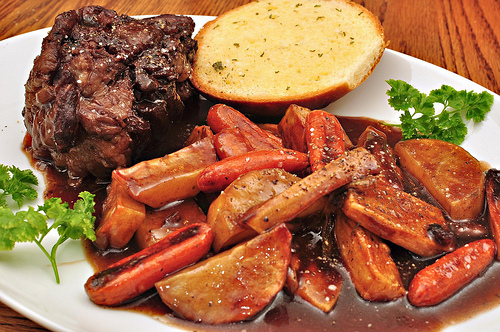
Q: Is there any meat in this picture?
A: Yes, there is meat.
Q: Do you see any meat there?
A: Yes, there is meat.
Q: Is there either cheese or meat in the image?
A: Yes, there is meat.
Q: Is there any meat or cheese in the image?
A: Yes, there is meat.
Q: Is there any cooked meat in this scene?
A: Yes, there is cooked meat.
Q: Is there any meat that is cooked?
A: Yes, there is meat that is cooked.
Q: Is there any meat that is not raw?
A: Yes, there is cooked meat.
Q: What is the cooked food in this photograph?
A: The food is meat.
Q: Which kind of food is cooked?
A: The food is meat.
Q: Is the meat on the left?
A: Yes, the meat is on the left of the image.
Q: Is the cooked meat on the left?
A: Yes, the meat is on the left of the image.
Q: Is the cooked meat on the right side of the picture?
A: No, the meat is on the left of the image.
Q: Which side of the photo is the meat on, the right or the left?
A: The meat is on the left of the image.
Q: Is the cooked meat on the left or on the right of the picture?
A: The meat is on the left of the image.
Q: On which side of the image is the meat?
A: The meat is on the left of the image.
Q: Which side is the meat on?
A: The meat is on the left of the image.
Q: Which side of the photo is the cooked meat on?
A: The meat is on the left of the image.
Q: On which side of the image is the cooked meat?
A: The meat is on the left of the image.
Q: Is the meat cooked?
A: Yes, the meat is cooked.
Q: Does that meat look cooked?
A: Yes, the meat is cooked.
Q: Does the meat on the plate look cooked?
A: Yes, the meat is cooked.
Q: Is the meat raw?
A: No, the meat is cooked.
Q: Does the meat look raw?
A: No, the meat is cooked.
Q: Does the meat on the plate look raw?
A: No, the meat is cooked.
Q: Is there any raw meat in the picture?
A: No, there is meat but it is cooked.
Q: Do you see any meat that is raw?
A: No, there is meat but it is cooked.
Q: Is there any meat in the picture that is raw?
A: No, there is meat but it is cooked.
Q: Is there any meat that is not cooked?
A: No, there is meat but it is cooked.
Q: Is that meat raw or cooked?
A: The meat is cooked.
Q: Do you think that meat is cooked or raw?
A: The meat is cooked.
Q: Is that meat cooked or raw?
A: The meat is cooked.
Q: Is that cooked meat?
A: Yes, that is cooked meat.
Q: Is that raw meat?
A: No, that is cooked meat.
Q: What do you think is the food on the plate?
A: The food is meat.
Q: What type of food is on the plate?
A: The food is meat.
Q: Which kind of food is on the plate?
A: The food is meat.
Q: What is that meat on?
A: The meat is on the plate.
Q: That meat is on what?
A: The meat is on the plate.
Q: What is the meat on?
A: The meat is on the plate.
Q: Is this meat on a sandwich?
A: No, the meat is on the plate.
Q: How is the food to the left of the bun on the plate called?
A: The food is meat.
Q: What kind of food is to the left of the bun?
A: The food is meat.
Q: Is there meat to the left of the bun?
A: Yes, there is meat to the left of the bun.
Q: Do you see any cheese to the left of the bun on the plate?
A: No, there is meat to the left of the bun.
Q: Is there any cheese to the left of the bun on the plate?
A: No, there is meat to the left of the bun.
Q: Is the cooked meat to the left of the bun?
A: Yes, the meat is to the left of the bun.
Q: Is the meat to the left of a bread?
A: No, the meat is to the left of the bun.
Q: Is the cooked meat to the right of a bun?
A: No, the meat is to the left of a bun.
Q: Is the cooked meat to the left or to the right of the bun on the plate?
A: The meat is to the left of the bun.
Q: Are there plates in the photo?
A: Yes, there is a plate.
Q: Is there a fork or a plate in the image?
A: Yes, there is a plate.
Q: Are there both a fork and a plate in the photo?
A: No, there is a plate but no forks.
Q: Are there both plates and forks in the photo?
A: No, there is a plate but no forks.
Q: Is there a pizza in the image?
A: No, there are no pizzas.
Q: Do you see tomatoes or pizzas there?
A: No, there are no pizzas or tomatoes.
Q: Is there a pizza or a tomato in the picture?
A: No, there are no pizzas or tomatoes.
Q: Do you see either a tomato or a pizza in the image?
A: No, there are no pizzas or tomatoes.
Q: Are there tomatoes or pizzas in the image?
A: No, there are no pizzas or tomatoes.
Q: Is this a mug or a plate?
A: This is a plate.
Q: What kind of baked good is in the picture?
A: The baked good is a bun.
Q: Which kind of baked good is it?
A: The food is a bun.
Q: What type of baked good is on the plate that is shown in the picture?
A: The food is a bun.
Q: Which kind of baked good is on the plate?
A: The food is a bun.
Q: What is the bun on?
A: The bun is on the plate.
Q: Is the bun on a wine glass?
A: No, the bun is on the plate.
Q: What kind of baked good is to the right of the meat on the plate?
A: The food is a bun.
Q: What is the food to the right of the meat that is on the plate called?
A: The food is a bun.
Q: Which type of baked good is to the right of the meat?
A: The food is a bun.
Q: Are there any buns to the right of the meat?
A: Yes, there is a bun to the right of the meat.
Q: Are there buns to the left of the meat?
A: No, the bun is to the right of the meat.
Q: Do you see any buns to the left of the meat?
A: No, the bun is to the right of the meat.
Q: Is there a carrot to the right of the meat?
A: No, there is a bun to the right of the meat.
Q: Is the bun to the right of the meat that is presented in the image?
A: Yes, the bun is to the right of the meat.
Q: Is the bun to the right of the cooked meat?
A: Yes, the bun is to the right of the meat.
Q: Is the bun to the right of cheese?
A: No, the bun is to the right of the meat.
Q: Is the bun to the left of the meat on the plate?
A: No, the bun is to the right of the meat.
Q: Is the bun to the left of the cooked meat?
A: No, the bun is to the right of the meat.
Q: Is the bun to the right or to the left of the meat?
A: The bun is to the right of the meat.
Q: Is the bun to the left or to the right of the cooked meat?
A: The bun is to the right of the meat.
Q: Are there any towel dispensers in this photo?
A: No, there are no towel dispensers.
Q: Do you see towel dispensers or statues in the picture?
A: No, there are no towel dispensers or statues.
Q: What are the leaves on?
A: The leaves are on the plate.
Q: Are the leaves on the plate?
A: Yes, the leaves are on the plate.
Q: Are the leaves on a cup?
A: No, the leaves are on the plate.